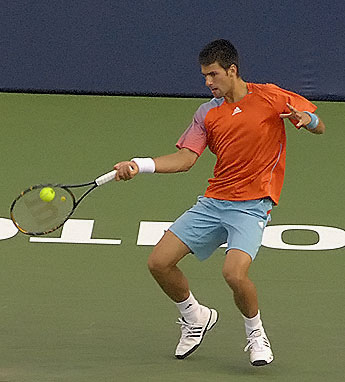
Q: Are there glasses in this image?
A: No, there are no glasses.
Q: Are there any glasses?
A: No, there are no glasses.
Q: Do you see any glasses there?
A: No, there are no glasses.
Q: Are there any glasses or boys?
A: No, there are no glasses or boys.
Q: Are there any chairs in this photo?
A: No, there are no chairs.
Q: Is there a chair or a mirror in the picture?
A: No, there are no chairs or mirrors.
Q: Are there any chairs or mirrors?
A: No, there are no chairs or mirrors.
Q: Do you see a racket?
A: Yes, there is a racket.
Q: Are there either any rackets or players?
A: Yes, there is a racket.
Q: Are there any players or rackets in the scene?
A: Yes, there is a racket.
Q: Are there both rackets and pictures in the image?
A: No, there is a racket but no pictures.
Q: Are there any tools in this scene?
A: No, there are no tools.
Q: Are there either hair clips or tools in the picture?
A: No, there are no tools or hair clips.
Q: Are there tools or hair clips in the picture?
A: No, there are no tools or hair clips.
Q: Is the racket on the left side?
A: Yes, the racket is on the left of the image.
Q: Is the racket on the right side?
A: No, the racket is on the left of the image.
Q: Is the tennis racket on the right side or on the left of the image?
A: The tennis racket is on the left of the image.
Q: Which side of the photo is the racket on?
A: The racket is on the left of the image.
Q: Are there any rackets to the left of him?
A: Yes, there is a racket to the left of the man.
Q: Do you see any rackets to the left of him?
A: Yes, there is a racket to the left of the man.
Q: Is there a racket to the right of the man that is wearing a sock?
A: No, the racket is to the left of the man.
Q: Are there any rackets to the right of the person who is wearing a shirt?
A: No, the racket is to the left of the man.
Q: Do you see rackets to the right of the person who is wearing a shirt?
A: No, the racket is to the left of the man.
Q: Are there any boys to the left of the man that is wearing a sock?
A: No, there is a racket to the left of the man.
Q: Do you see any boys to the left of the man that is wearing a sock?
A: No, there is a racket to the left of the man.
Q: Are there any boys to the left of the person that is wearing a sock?
A: No, there is a racket to the left of the man.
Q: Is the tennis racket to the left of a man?
A: Yes, the tennis racket is to the left of a man.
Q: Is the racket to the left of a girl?
A: No, the racket is to the left of a man.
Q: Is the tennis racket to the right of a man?
A: No, the tennis racket is to the left of a man.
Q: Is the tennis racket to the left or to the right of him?
A: The tennis racket is to the left of the man.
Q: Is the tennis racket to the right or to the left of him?
A: The tennis racket is to the left of the man.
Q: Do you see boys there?
A: No, there are no boys.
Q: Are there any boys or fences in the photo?
A: No, there are no boys or fences.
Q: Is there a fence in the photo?
A: No, there are no fences.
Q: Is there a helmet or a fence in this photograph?
A: No, there are no fences or helmets.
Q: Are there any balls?
A: Yes, there is a ball.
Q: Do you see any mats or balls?
A: Yes, there is a ball.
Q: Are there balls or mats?
A: Yes, there is a ball.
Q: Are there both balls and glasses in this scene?
A: No, there is a ball but no glasses.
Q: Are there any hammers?
A: No, there are no hammers.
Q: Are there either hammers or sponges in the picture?
A: No, there are no hammers or sponges.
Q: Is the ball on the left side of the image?
A: Yes, the ball is on the left of the image.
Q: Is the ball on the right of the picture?
A: No, the ball is on the left of the image.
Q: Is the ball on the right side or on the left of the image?
A: The ball is on the left of the image.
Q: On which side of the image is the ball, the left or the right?
A: The ball is on the left of the image.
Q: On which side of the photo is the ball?
A: The ball is on the left of the image.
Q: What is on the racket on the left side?
A: The ball is on the tennis racket.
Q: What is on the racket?
A: The ball is on the tennis racket.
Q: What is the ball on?
A: The ball is on the tennis racket.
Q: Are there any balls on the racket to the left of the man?
A: Yes, there is a ball on the tennis racket.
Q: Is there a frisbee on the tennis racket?
A: No, there is a ball on the tennis racket.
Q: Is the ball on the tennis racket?
A: Yes, the ball is on the tennis racket.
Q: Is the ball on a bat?
A: No, the ball is on the tennis racket.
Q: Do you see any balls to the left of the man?
A: Yes, there is a ball to the left of the man.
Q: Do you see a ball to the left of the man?
A: Yes, there is a ball to the left of the man.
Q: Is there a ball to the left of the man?
A: Yes, there is a ball to the left of the man.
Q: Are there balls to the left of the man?
A: Yes, there is a ball to the left of the man.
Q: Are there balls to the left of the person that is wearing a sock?
A: Yes, there is a ball to the left of the man.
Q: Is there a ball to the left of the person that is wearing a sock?
A: Yes, there is a ball to the left of the man.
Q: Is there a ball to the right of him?
A: No, the ball is to the left of the man.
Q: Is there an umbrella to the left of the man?
A: No, there is a ball to the left of the man.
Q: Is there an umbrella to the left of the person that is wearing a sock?
A: No, there is a ball to the left of the man.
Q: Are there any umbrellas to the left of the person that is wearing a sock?
A: No, there is a ball to the left of the man.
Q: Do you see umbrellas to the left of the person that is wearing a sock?
A: No, there is a ball to the left of the man.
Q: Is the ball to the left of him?
A: Yes, the ball is to the left of the man.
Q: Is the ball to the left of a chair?
A: No, the ball is to the left of the man.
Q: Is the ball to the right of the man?
A: No, the ball is to the left of the man.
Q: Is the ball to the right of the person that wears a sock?
A: No, the ball is to the left of the man.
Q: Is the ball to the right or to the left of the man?
A: The ball is to the left of the man.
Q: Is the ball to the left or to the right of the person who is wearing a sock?
A: The ball is to the left of the man.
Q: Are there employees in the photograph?
A: No, there are no employees.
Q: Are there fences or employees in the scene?
A: No, there are no employees or fences.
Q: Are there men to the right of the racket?
A: Yes, there is a man to the right of the racket.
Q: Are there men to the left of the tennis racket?
A: No, the man is to the right of the tennis racket.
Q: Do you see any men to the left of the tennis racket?
A: No, the man is to the right of the tennis racket.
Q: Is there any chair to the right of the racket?
A: No, there is a man to the right of the racket.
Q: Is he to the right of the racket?
A: Yes, the man is to the right of the racket.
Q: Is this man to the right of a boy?
A: No, the man is to the right of the racket.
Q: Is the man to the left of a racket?
A: No, the man is to the right of a racket.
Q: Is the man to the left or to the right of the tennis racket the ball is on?
A: The man is to the right of the racket.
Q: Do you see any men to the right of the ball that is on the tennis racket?
A: Yes, there is a man to the right of the ball.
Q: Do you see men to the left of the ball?
A: No, the man is to the right of the ball.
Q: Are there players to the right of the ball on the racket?
A: No, there is a man to the right of the ball.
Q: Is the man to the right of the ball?
A: Yes, the man is to the right of the ball.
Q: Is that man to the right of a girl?
A: No, the man is to the right of the ball.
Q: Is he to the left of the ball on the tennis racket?
A: No, the man is to the right of the ball.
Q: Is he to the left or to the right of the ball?
A: The man is to the right of the ball.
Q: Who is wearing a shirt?
A: The man is wearing a shirt.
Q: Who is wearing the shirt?
A: The man is wearing a shirt.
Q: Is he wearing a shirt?
A: Yes, the man is wearing a shirt.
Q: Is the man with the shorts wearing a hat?
A: No, the man is wearing a shirt.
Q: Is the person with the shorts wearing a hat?
A: No, the man is wearing a shirt.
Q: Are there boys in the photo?
A: No, there are no boys.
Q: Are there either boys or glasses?
A: No, there are no boys or glasses.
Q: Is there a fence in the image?
A: No, there are no fences.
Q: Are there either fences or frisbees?
A: No, there are no fences or frisbees.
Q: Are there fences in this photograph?
A: No, there are no fences.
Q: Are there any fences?
A: No, there are no fences.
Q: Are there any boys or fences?
A: No, there are no fences or boys.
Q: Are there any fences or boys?
A: No, there are no fences or boys.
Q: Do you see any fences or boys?
A: No, there are no fences or boys.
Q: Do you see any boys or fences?
A: No, there are no fences or boys.